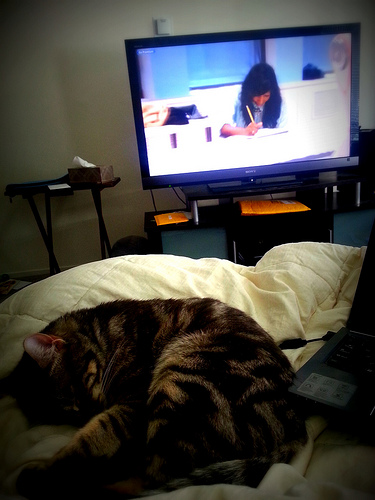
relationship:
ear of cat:
[22, 329, 63, 364] [2, 293, 310, 497]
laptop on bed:
[276, 253, 363, 430] [2, 237, 374, 498]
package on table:
[153, 209, 187, 226] [135, 201, 362, 265]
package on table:
[236, 197, 310, 218] [144, 195, 363, 255]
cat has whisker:
[2, 293, 310, 497] [97, 352, 124, 395]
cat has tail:
[2, 293, 310, 497] [72, 439, 295, 498]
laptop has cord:
[285, 225, 375, 420] [275, 330, 332, 351]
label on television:
[242, 167, 258, 175] [122, 20, 360, 193]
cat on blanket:
[2, 293, 310, 497] [4, 236, 361, 498]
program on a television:
[131, 31, 343, 176] [122, 20, 360, 193]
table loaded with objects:
[5, 162, 124, 275] [18, 153, 103, 203]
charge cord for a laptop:
[276, 327, 334, 352] [285, 225, 375, 420]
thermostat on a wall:
[153, 16, 177, 36] [3, 4, 372, 293]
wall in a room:
[3, 4, 372, 293] [2, 1, 372, 491]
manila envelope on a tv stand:
[236, 193, 308, 214] [220, 192, 339, 271]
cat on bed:
[2, 293, 310, 497] [2, 237, 374, 498]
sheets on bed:
[4, 237, 370, 497] [2, 237, 374, 498]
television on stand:
[124, 18, 363, 190] [148, 183, 333, 262]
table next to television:
[11, 162, 124, 272] [124, 18, 363, 190]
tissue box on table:
[66, 154, 105, 190] [11, 162, 124, 272]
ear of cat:
[17, 327, 60, 362] [2, 293, 310, 497]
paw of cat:
[56, 428, 101, 456] [2, 293, 310, 497]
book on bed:
[283, 333, 374, 414] [2, 237, 374, 498]